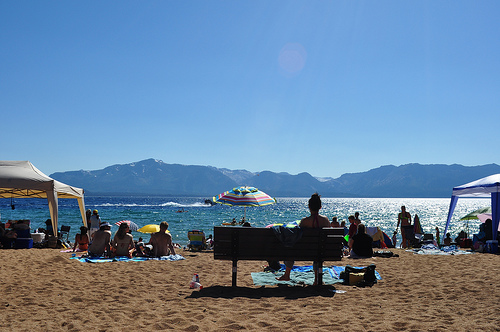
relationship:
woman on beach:
[276, 194, 331, 286] [0, 248, 499, 331]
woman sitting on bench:
[276, 194, 331, 286] [213, 227, 345, 285]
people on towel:
[88, 221, 176, 258] [69, 255, 183, 264]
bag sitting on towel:
[341, 263, 377, 284] [251, 266, 381, 284]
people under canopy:
[444, 218, 492, 244] [439, 174, 499, 245]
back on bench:
[213, 227, 342, 261] [213, 227, 345, 285]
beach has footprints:
[0, 248, 499, 331] [0, 250, 499, 331]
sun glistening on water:
[276, 195, 492, 252] [3, 198, 493, 248]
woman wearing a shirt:
[348, 223, 375, 258] [351, 233, 373, 256]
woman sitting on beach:
[348, 223, 375, 258] [0, 248, 499, 331]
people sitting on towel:
[88, 221, 176, 258] [69, 255, 183, 264]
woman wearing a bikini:
[395, 206, 412, 248] [399, 213, 411, 229]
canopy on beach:
[439, 174, 499, 245] [0, 248, 499, 331]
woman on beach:
[395, 206, 412, 248] [0, 248, 499, 331]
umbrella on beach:
[116, 219, 140, 233] [0, 248, 499, 331]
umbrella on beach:
[139, 223, 170, 233] [0, 248, 499, 331]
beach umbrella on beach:
[213, 184, 276, 207] [0, 248, 499, 331]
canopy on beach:
[1, 159, 88, 234] [0, 248, 499, 331]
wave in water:
[104, 201, 214, 209] [3, 198, 493, 248]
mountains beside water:
[48, 157, 499, 199] [3, 198, 493, 248]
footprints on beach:
[0, 250, 499, 331] [0, 248, 499, 331]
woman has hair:
[276, 194, 331, 286] [309, 193, 322, 210]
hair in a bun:
[309, 193, 322, 210] [311, 194, 322, 202]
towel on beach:
[69, 255, 183, 264] [0, 248, 499, 331]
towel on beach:
[251, 266, 381, 284] [0, 248, 499, 331]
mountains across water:
[48, 157, 499, 199] [3, 198, 493, 248]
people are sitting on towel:
[88, 221, 176, 258] [69, 255, 183, 264]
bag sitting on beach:
[341, 263, 377, 284] [0, 248, 499, 331]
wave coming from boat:
[104, 201, 214, 209] [205, 198, 218, 204]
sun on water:
[276, 195, 492, 252] [3, 198, 493, 248]